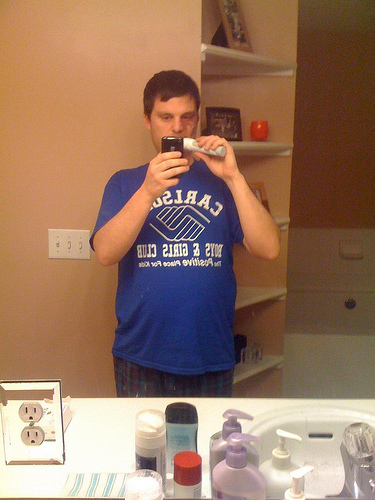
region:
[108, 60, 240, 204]
Man is brushing his teeth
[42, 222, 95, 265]
Light switches on the wall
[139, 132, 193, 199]
Cell phone in a hand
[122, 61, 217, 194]
Man is taking a selfie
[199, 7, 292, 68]
A photo frame on a shelf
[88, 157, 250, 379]
White writing on a blue shirt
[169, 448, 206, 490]
Red cap on a bottle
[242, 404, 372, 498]
A faucet over a sink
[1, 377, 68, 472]
An electrical outlet on the mirror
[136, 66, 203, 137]
Man has brown hair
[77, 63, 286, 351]
A person brushing his teeth in the bathroom mirror.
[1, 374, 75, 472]
An electrical outlet on the bathroom mirror.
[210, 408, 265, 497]
Lotion on the counter in the bathroom mirror.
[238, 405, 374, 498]
The bathroom sink in the bathroom mirror.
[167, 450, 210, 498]
Shaving cream in the bathroom mirror.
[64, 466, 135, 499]
A towel on the counter and in the bathroom mirror.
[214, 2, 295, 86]
A picture in the bathroom mirror.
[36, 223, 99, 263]
Light switches reflecting in the bathroom mirror.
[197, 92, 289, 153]
A picture and candle in the bathroom mirror.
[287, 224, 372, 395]
A bath tub reflecting in the bathroom mirror.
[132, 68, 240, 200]
boy looking at phone while brushing teeth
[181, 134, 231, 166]
hand holding electric toothbrush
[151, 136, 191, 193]
hand holding black cellphone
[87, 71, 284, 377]
a boy wearing a Boy's Club t-shirt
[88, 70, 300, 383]
a boy wearing a blue t-shirt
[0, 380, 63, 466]
a wall socket on a mirror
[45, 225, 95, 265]
three light switches on the wall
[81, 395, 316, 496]
a counter full of toiletries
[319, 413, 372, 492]
the faucet to a sink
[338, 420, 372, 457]
clear plastic handle to a faucet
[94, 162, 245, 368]
the man wears a blue shirt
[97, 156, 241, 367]
the man wears a short sleeve shirt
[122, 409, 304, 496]
the counter has many bottles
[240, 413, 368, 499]
the sink is dirty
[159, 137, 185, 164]
the man takes a photo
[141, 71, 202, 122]
the man has short hair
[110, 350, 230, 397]
the man wears plaid pants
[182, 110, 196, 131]
the man has a scar on his face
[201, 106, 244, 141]
picture frame on shelf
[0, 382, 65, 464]
a mirrored outlet on mirror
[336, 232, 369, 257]
a white soap dish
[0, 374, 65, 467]
a wall outlet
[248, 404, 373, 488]
part of a white sink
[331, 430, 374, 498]
part of a sink faucet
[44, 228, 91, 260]
a white wall light switch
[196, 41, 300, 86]
a white shelf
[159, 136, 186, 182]
a black cellphone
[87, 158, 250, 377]
a man's blue and white shirt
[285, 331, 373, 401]
part of a white tub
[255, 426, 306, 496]
part of a white lotion bottle